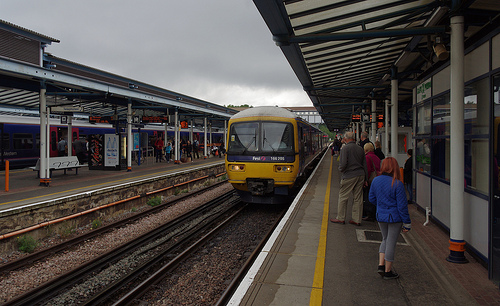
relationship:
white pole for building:
[448, 15, 466, 262] [253, 0, 498, 302]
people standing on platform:
[326, 118, 411, 283] [221, 134, 496, 302]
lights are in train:
[231, 161, 293, 176] [222, 107, 324, 207]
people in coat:
[326, 118, 411, 283] [369, 174, 411, 224]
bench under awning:
[28, 153, 91, 180] [6, 60, 246, 131]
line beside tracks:
[306, 153, 333, 304] [0, 175, 293, 304]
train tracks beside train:
[156, 197, 250, 303] [217, 99, 327, 184]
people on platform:
[326, 118, 411, 283] [213, 139, 476, 291]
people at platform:
[326, 118, 411, 283] [234, 137, 467, 297]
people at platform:
[136, 129, 224, 160] [7, 136, 227, 225]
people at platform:
[326, 118, 411, 283] [221, 134, 496, 302]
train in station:
[217, 96, 304, 211] [0, 9, 497, 304]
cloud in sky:
[195, 82, 267, 102] [1, 1, 321, 109]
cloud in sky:
[195, 82, 267, 102] [15, 9, 312, 103]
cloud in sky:
[195, 82, 267, 102] [85, 6, 202, 97]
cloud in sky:
[195, 82, 267, 102] [106, 12, 246, 84]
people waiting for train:
[326, 118, 411, 283] [220, 95, 345, 200]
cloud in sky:
[195, 82, 267, 102] [139, 16, 296, 107]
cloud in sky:
[195, 82, 267, 102] [36, 0, 313, 117]